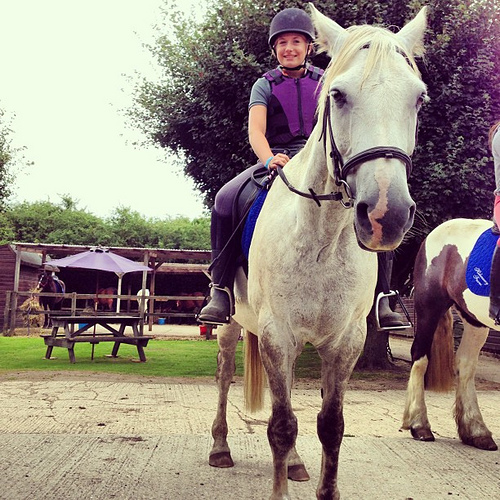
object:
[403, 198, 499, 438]
horse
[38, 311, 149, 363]
bench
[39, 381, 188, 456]
cement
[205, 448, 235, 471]
hoof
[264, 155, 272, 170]
bracelet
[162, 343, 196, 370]
grass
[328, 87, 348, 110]
eye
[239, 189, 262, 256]
blanket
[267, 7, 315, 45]
helmet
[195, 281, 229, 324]
boots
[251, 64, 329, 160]
tshirt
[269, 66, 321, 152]
vest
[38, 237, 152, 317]
umbrella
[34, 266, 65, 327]
horse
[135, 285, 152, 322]
horse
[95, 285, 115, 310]
horse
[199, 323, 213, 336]
bucket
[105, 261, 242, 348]
fence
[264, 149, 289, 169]
hand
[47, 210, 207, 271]
trees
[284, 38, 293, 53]
nose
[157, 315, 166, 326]
bucket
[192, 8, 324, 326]
lady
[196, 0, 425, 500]
horse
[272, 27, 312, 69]
head